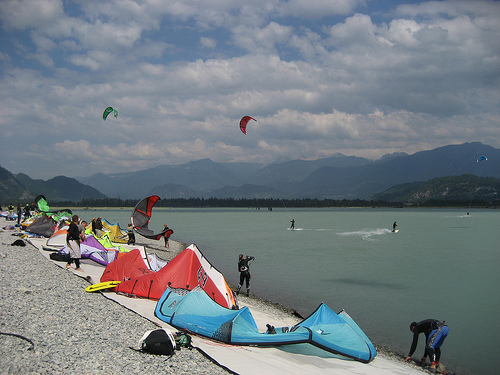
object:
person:
[289, 219, 296, 230]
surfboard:
[85, 281, 123, 293]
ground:
[68, 282, 84, 316]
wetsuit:
[290, 221, 295, 230]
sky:
[0, 0, 500, 181]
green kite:
[102, 106, 118, 121]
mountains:
[0, 142, 500, 206]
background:
[0, 0, 500, 206]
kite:
[153, 285, 377, 365]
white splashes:
[335, 227, 391, 241]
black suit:
[236, 257, 256, 297]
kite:
[238, 115, 258, 136]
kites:
[475, 155, 487, 163]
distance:
[0, 0, 500, 213]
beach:
[0, 194, 499, 375]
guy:
[403, 318, 450, 372]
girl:
[236, 254, 256, 297]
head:
[238, 254, 244, 260]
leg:
[246, 277, 252, 297]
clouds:
[221, 26, 357, 100]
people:
[391, 221, 399, 232]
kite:
[58, 235, 119, 266]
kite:
[130, 194, 174, 241]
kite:
[85, 217, 132, 243]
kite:
[37, 197, 50, 212]